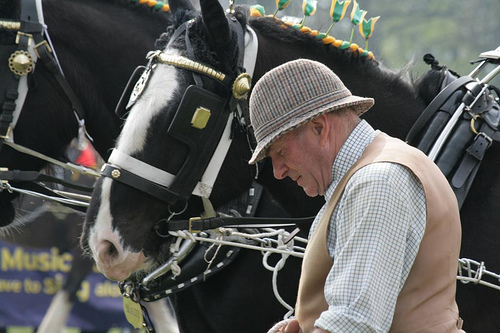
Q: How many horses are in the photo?
A: Two.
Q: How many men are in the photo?
A: One.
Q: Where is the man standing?
A: Next to the horse.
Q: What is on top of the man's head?
A: A hat.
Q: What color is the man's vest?
A: Brown.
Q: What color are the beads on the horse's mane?
A: Orange and green.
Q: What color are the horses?
A: Black and white.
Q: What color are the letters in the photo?
A: Yellow.